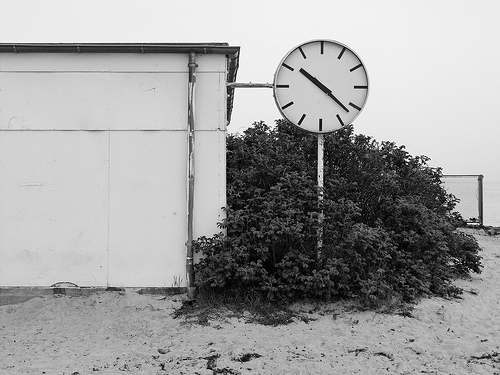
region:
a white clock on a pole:
[265, 25, 387, 297]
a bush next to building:
[134, 110, 480, 340]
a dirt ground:
[6, 205, 491, 373]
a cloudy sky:
[3, 0, 495, 180]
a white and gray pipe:
[172, 37, 212, 323]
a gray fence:
[421, 164, 497, 226]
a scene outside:
[8, 0, 485, 370]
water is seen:
[416, 160, 498, 231]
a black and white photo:
[6, 52, 424, 373]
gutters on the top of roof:
[1, 40, 254, 90]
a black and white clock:
[264, 34, 371, 144]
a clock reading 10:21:
[261, 32, 373, 145]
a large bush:
[178, 111, 482, 320]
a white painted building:
[0, 38, 251, 290]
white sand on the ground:
[0, 309, 497, 374]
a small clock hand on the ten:
[294, 64, 324, 89]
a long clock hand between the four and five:
[312, 73, 355, 118]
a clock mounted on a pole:
[265, 33, 374, 279]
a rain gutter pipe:
[180, 47, 204, 307]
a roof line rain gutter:
[3, 34, 242, 55]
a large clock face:
[267, 40, 381, 137]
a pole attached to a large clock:
[312, 135, 332, 287]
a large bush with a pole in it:
[227, 128, 483, 328]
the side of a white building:
[2, 63, 152, 287]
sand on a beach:
[40, 310, 372, 371]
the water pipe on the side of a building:
[180, 58, 204, 280]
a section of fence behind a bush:
[449, 169, 495, 233]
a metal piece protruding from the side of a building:
[229, 76, 274, 101]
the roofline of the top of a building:
[5, 32, 234, 52]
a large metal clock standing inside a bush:
[269, 29, 382, 289]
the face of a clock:
[253, 22, 380, 145]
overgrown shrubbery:
[228, 126, 466, 308]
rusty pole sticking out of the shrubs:
[304, 138, 340, 280]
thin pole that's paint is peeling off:
[180, 53, 207, 285]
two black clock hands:
[295, 56, 351, 116]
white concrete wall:
[4, 51, 230, 288]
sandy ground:
[13, 298, 498, 374]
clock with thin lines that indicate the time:
[265, 29, 385, 144]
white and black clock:
[260, 36, 384, 158]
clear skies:
[1, 3, 498, 207]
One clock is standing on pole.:
[261, 39, 398, 149]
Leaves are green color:
[265, 11, 312, 189]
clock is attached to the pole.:
[255, 45, 370, 207]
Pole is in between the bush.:
[273, 146, 360, 259]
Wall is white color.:
[34, 128, 147, 228]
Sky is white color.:
[393, 37, 460, 127]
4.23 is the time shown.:
[276, 32, 371, 132]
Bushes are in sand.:
[38, 276, 423, 362]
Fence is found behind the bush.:
[431, 146, 499, 243]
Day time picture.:
[14, 17, 428, 348]